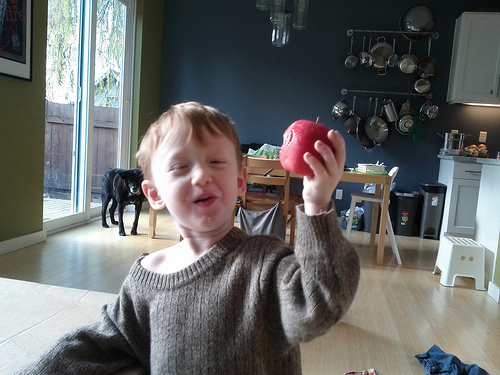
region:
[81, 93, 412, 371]
A little boy.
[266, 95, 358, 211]
The boy is holding an apple.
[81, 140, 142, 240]
A black dog.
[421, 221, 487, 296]
A white stool.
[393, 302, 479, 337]
The wood floor.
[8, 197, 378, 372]
The boy is wearing a sweater.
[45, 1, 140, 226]
A sliding glass window.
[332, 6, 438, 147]
Pans hanging from the wall.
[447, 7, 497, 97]
A white cabinet.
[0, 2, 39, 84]
A framed picture on the wall.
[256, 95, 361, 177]
red delicous apple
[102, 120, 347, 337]
little boy wearing a gray sweater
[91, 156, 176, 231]
black dog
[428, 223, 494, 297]
white short step stool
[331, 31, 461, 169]
an assortment of silver pots and pans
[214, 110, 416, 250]
wood table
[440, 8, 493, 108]
white kitchen cabinet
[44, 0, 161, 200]
sliding glass window doors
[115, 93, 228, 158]
reddish blonde hair on the boy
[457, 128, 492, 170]
oranges on the table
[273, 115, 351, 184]
an apple holding by a cute boy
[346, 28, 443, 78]
a group of cooking wares hangings on the wall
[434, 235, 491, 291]
a white chair placing near by wall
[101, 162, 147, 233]
a black dog standing near the door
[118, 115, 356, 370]
a cute boy holding an apple and enjoying it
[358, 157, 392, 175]
a plastic box placed on the wooden table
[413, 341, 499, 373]
a jeans pant thrown on the floor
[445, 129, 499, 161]
fruits and other items placed the cupboard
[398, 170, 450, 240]
two dustbin boxes placed left to the cupboard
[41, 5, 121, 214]
two glass doors attached to the wall for entrance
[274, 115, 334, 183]
red apple in kid's hand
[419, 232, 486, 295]
white stool in kitchen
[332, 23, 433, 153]
pots and pans hanging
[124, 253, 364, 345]
kid wearing grey sweater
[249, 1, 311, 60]
lamp hanging from ceiling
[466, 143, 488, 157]
fruit on counter top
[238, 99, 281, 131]
navy blue wall in back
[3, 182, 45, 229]
green wall on side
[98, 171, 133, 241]
black dog standing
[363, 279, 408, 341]
floor is made of wood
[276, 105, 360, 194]
Red apple in a boy's hand.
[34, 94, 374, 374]
Boy wearing a brown sweater.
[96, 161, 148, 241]
Dog with black hair.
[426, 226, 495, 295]
White step stool with blue dots on top.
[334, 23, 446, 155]
Stainless steel pots and pans hanging on the wall.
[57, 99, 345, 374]
Small boy holding a red apple.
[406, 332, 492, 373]
Clothing sitting on the floor.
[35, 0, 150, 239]
Sliding glass doors leading to the outside.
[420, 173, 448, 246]
Stainless steel trash can with a black lid.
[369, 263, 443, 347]
Hardwood covering the floor.